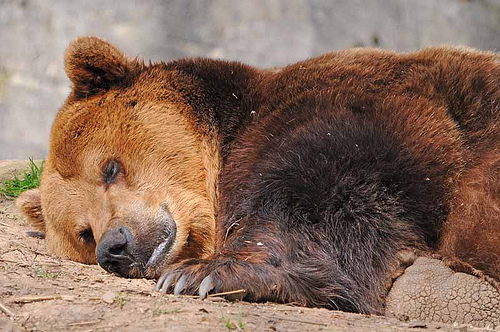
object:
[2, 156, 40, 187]
grass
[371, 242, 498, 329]
paw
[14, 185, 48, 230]
ear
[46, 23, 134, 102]
ear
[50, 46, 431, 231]
bear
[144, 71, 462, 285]
fur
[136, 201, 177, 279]
mouth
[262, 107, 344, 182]
fur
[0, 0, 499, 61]
background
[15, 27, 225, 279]
straw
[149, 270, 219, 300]
claws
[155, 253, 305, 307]
hand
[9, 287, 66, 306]
twig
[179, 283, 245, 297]
twig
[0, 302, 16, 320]
twig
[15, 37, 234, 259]
head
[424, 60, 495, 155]
brown spot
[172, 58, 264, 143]
brown spot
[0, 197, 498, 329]
dirt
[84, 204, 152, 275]
nose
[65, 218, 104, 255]
eye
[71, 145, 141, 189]
eyes